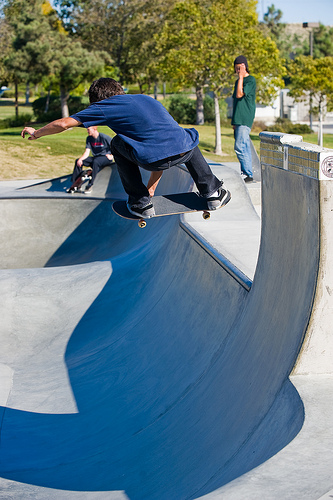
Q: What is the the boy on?
A: A skateboard.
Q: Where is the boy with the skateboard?
A: On the edge of the skating ring.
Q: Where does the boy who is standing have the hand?
A: On the face.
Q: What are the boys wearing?
A: T-shirt and jeans.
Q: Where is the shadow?
A: On the skating ramp.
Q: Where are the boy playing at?
A: The skating ramp.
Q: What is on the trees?
A: Leaves.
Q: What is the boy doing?
A: Skateboard.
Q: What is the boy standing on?
A: Skateboard.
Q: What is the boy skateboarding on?
A: Skate ramp.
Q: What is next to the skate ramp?
A: Grass.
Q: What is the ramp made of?
A: Cement.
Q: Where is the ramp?
A: In skatepark.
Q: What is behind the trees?
A: Building.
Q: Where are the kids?
A: A skateboard park.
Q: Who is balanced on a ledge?
A: A boy in a blue shirt on a skateboard.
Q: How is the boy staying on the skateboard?
A: Using both feet.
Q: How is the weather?
A: Clear and sunny.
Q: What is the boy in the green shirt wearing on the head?
A: A blue hat.`.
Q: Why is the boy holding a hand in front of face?
A: To block out sunlight.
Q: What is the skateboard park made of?
A: Cement.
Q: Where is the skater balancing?
A: The edge.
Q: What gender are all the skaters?
A: Male.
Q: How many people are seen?
A: 3.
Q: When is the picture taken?
A: Daytime.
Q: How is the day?
A: Sunny.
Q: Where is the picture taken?
A: At a skate ramp.